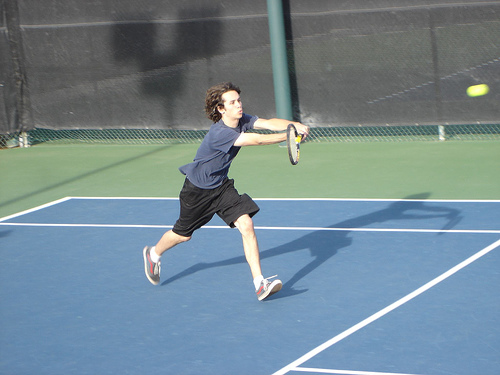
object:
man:
[140, 79, 310, 303]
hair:
[205, 82, 241, 121]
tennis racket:
[288, 122, 311, 166]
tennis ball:
[467, 82, 488, 98]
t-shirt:
[179, 114, 257, 191]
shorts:
[172, 176, 258, 238]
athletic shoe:
[139, 244, 162, 283]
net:
[1, 2, 499, 141]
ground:
[1, 138, 497, 374]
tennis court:
[1, 132, 499, 373]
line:
[2, 218, 499, 238]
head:
[205, 84, 242, 125]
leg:
[220, 189, 270, 285]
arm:
[214, 126, 289, 147]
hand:
[294, 123, 310, 135]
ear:
[216, 105, 226, 114]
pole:
[269, 1, 296, 147]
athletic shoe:
[253, 278, 282, 301]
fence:
[2, 2, 499, 139]